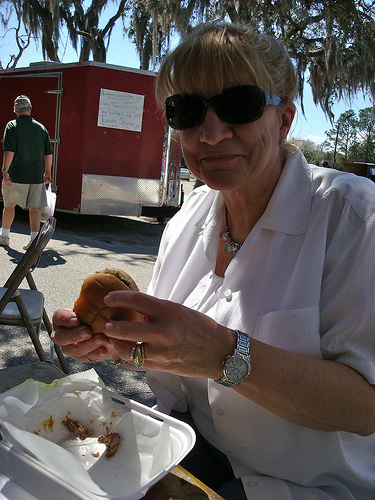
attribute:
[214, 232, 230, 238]
trinket — silver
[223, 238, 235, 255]
trinket — silver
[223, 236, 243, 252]
trinket — silver